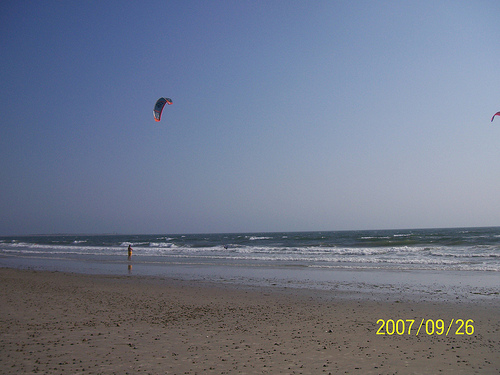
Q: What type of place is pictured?
A: It is a beach.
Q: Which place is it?
A: It is a beach.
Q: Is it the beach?
A: Yes, it is the beach.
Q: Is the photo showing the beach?
A: Yes, it is showing the beach.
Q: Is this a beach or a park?
A: It is a beach.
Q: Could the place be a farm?
A: No, it is a beach.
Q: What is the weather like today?
A: It is clear.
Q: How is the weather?
A: It is clear.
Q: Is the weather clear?
A: Yes, it is clear.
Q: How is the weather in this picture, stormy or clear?
A: It is clear.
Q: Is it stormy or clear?
A: It is clear.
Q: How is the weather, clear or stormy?
A: It is clear.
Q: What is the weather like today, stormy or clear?
A: It is clear.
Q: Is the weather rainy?
A: No, it is clear.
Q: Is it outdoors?
A: Yes, it is outdoors.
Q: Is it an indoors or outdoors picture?
A: It is outdoors.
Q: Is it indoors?
A: No, it is outdoors.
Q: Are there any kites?
A: Yes, there is a kite.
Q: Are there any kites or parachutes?
A: Yes, there is a kite.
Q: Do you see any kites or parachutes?
A: Yes, there is a kite.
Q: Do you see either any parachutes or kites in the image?
A: Yes, there is a kite.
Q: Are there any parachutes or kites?
A: Yes, there is a kite.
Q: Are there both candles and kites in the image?
A: No, there is a kite but no candles.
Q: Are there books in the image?
A: No, there are no books.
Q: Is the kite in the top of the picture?
A: Yes, the kite is in the top of the image.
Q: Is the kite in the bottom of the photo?
A: No, the kite is in the top of the image.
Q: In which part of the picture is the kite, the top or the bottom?
A: The kite is in the top of the image.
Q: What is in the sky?
A: The kite is in the sky.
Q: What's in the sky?
A: The kite is in the sky.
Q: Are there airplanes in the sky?
A: No, there is a kite in the sky.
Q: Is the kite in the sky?
A: Yes, the kite is in the sky.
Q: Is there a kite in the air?
A: Yes, there is a kite in the air.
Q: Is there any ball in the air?
A: No, there is a kite in the air.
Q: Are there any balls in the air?
A: No, there is a kite in the air.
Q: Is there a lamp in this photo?
A: No, there are no lamps.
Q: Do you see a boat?
A: No, there are no boats.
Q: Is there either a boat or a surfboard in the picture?
A: No, there are no boats or surfboards.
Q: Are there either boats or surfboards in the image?
A: No, there are no boats or surfboards.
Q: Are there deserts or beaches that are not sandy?
A: No, there is a beach but it is sandy.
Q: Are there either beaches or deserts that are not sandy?
A: No, there is a beach but it is sandy.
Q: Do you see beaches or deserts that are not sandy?
A: No, there is a beach but it is sandy.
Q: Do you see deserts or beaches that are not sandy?
A: No, there is a beach but it is sandy.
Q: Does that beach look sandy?
A: Yes, the beach is sandy.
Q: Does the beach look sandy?
A: Yes, the beach is sandy.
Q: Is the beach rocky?
A: No, the beach is sandy.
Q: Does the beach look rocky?
A: No, the beach is sandy.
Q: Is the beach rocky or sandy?
A: The beach is sandy.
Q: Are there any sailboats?
A: No, there are no sailboats.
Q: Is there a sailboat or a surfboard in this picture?
A: No, there are no sailboats or surfboards.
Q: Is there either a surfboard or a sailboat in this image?
A: No, there are no sailboats or surfboards.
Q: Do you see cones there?
A: No, there are no cones.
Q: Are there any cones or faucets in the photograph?
A: No, there are no cones or faucets.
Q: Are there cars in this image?
A: No, there are no cars.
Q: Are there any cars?
A: No, there are no cars.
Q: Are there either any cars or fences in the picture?
A: No, there are no cars or fences.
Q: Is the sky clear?
A: Yes, the sky is clear.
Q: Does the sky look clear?
A: Yes, the sky is clear.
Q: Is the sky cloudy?
A: No, the sky is clear.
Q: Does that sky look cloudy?
A: No, the sky is clear.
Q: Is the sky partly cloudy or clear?
A: The sky is clear.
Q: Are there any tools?
A: No, there are no tools.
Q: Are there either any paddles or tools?
A: No, there are no tools or paddles.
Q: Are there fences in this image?
A: No, there are no fences.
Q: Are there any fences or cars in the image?
A: No, there are no fences or cars.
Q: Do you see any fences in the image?
A: No, there are no fences.